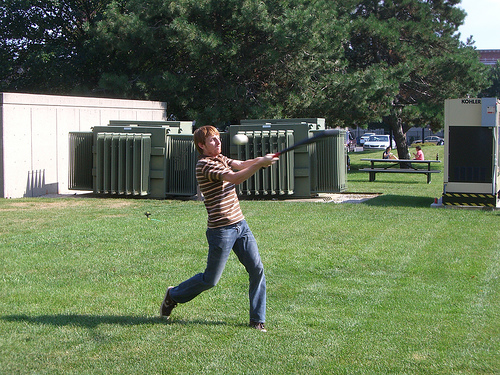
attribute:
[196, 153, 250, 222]
shirt — stripes, brown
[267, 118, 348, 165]
bat — white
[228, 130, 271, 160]
ball — white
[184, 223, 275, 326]
jeans — blue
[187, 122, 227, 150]
hair — red, ginger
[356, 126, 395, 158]
car — parked